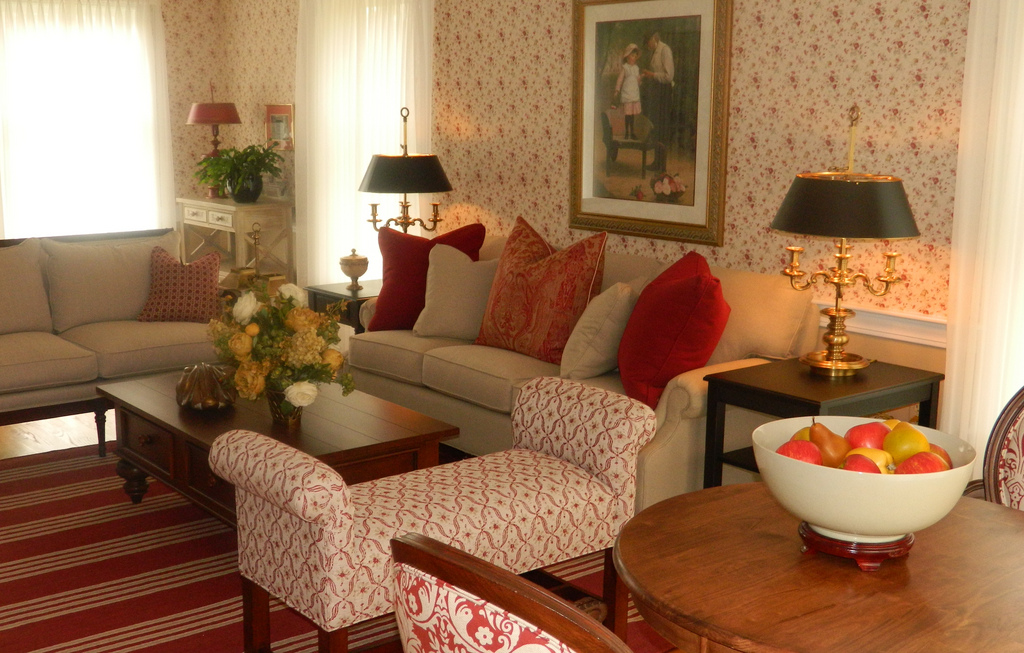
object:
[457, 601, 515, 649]
design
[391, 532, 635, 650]
chair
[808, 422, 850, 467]
fruit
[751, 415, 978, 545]
bowl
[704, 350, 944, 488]
table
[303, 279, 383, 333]
table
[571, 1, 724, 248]
picture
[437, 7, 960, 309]
wall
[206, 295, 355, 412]
bouquet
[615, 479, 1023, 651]
table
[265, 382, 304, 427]
vase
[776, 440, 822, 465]
fruits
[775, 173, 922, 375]
lamp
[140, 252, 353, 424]
arrangement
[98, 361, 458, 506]
table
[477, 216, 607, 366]
pillows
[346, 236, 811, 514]
sofa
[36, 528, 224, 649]
rug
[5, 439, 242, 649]
floor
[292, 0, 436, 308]
curtain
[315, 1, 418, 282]
window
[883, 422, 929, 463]
fruit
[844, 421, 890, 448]
fruits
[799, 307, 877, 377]
lamp holder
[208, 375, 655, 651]
sofa